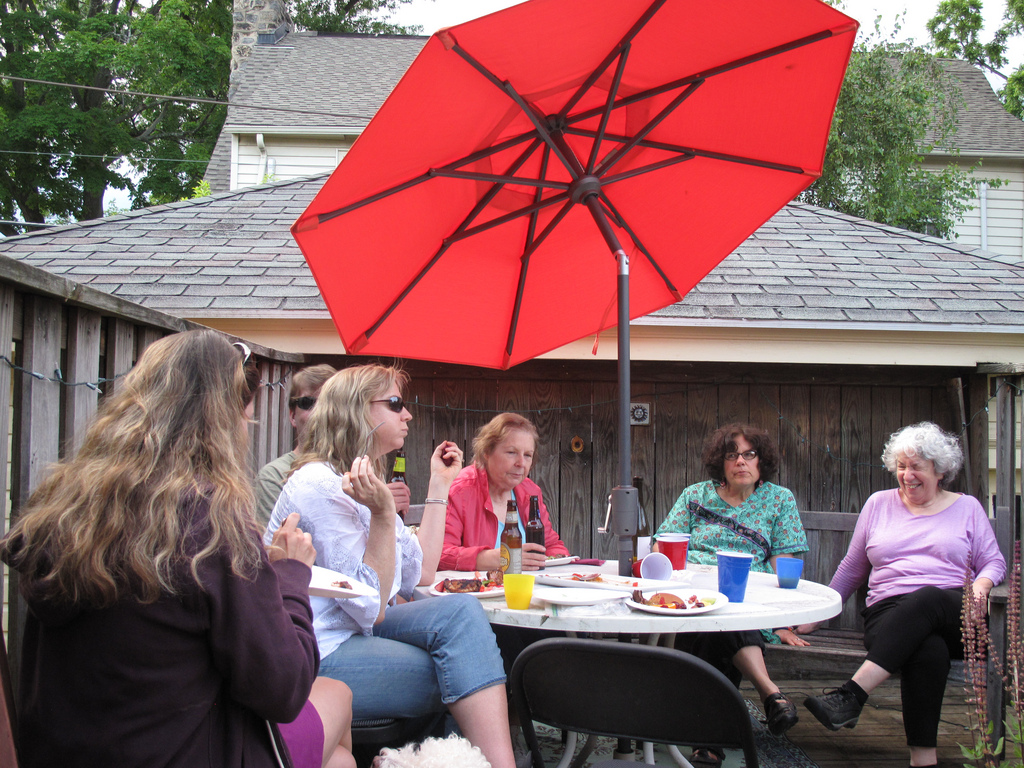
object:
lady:
[797, 418, 1005, 766]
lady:
[649, 423, 814, 734]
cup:
[715, 549, 751, 604]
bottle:
[388, 450, 408, 522]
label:
[392, 457, 405, 472]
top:
[647, 480, 816, 647]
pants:
[693, 634, 772, 655]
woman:
[647, 422, 812, 734]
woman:
[260, 360, 516, 766]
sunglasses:
[369, 395, 405, 414]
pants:
[314, 592, 511, 713]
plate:
[625, 588, 727, 615]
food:
[630, 590, 717, 612]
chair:
[515, 633, 758, 767]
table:
[403, 549, 843, 636]